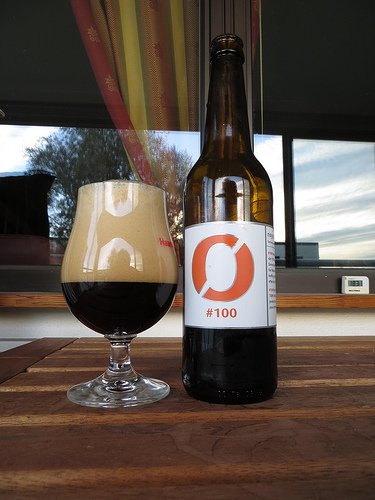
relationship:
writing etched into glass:
[145, 231, 176, 249] [59, 177, 176, 411]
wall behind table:
[0, 309, 372, 340] [0, 335, 374, 496]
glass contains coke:
[59, 177, 176, 411] [61, 178, 178, 340]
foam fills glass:
[58, 178, 179, 283] [59, 177, 176, 411]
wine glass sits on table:
[60, 180, 180, 411] [15, 326, 373, 457]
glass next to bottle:
[59, 177, 179, 411] [171, 24, 287, 409]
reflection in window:
[29, 122, 184, 254] [0, 9, 373, 302]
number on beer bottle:
[202, 304, 236, 316] [179, 33, 277, 407]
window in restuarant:
[254, 3, 374, 263] [25, 79, 316, 256]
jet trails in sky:
[254, 138, 373, 264] [0, 125, 373, 258]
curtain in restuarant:
[74, 8, 209, 171] [17, 76, 187, 247]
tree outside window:
[26, 125, 181, 179] [18, 127, 194, 240]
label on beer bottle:
[181, 218, 277, 329] [179, 30, 278, 405]